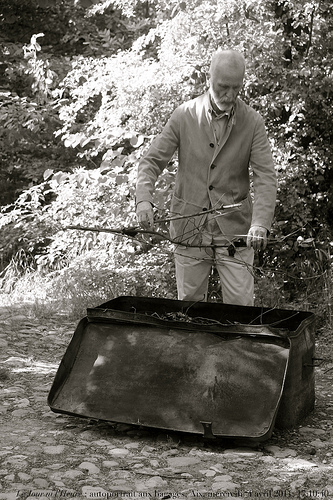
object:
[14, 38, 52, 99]
leaves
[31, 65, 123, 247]
beams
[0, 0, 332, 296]
fauna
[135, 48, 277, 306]
man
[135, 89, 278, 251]
blazer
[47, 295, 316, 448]
box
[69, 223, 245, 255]
branches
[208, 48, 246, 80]
his hair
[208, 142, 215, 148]
buttons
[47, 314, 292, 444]
open lid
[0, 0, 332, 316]
trees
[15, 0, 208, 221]
sunlight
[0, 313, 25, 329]
stones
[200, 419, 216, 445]
lock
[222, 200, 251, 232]
pocket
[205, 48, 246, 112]
head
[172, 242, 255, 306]
pants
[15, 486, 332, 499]
copyright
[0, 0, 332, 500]
photo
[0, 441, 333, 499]
ground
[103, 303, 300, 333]
twigs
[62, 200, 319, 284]
held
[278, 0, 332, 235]
bushes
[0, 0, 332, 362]
background